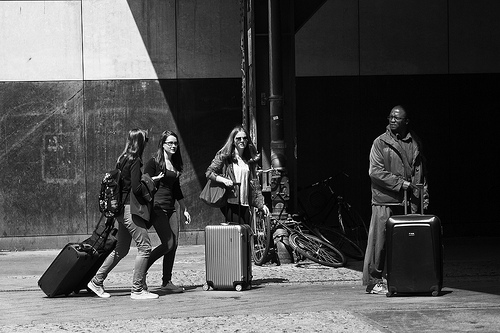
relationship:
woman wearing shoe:
[87, 128, 166, 301] [132, 290, 160, 300]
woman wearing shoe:
[87, 128, 166, 301] [88, 280, 111, 301]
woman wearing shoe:
[144, 129, 193, 293] [158, 283, 185, 293]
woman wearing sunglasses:
[205, 125, 271, 287] [233, 136, 249, 143]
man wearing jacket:
[362, 106, 429, 296] [369, 125, 429, 214]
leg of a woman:
[87, 214, 132, 297] [87, 128, 166, 301]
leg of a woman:
[120, 206, 161, 300] [87, 128, 166, 301]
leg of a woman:
[147, 203, 178, 268] [144, 129, 193, 293]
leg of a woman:
[161, 235, 185, 292] [144, 129, 193, 293]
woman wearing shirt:
[205, 125, 271, 287] [232, 154, 249, 209]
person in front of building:
[362, 106, 429, 296] [1, 2, 499, 237]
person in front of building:
[205, 125, 271, 287] [1, 2, 499, 237]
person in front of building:
[144, 129, 193, 293] [1, 2, 499, 237]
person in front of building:
[87, 128, 166, 301] [1, 2, 499, 237]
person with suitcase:
[362, 106, 429, 296] [384, 214, 441, 297]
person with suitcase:
[205, 125, 271, 287] [205, 222, 253, 290]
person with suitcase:
[87, 128, 166, 301] [38, 239, 101, 296]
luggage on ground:
[384, 214, 441, 297] [1, 245, 500, 333]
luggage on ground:
[205, 222, 253, 290] [1, 245, 500, 333]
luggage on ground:
[38, 239, 101, 296] [1, 245, 500, 333]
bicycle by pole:
[267, 208, 368, 267] [267, 2, 298, 265]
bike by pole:
[251, 197, 275, 264] [267, 2, 298, 265]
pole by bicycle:
[267, 2, 298, 265] [267, 208, 368, 267]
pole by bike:
[267, 2, 298, 265] [251, 197, 275, 264]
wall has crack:
[1, 2, 499, 237] [1, 83, 85, 161]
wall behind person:
[1, 2, 499, 237] [362, 106, 429, 296]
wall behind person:
[1, 2, 499, 237] [205, 125, 271, 287]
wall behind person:
[1, 2, 499, 237] [144, 129, 193, 293]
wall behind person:
[1, 2, 499, 237] [87, 128, 166, 301]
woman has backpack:
[87, 128, 166, 301] [97, 157, 142, 218]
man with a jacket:
[362, 106, 429, 296] [369, 125, 429, 214]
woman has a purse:
[205, 125, 271, 287] [197, 147, 233, 205]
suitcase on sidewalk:
[384, 214, 441, 297] [1, 276, 499, 332]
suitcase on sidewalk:
[205, 222, 253, 290] [1, 276, 499, 332]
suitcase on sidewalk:
[38, 239, 101, 296] [1, 276, 499, 332]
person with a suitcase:
[362, 106, 429, 296] [384, 214, 441, 297]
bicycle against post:
[267, 208, 368, 267] [267, 2, 298, 265]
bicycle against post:
[251, 197, 275, 264] [267, 2, 298, 265]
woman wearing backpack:
[87, 128, 166, 301] [97, 157, 142, 218]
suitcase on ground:
[384, 214, 441, 297] [1, 245, 500, 333]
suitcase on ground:
[205, 222, 253, 290] [1, 245, 500, 333]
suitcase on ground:
[38, 239, 101, 296] [1, 245, 500, 333]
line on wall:
[78, 4, 90, 234] [1, 2, 499, 237]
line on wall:
[176, 7, 180, 236] [1, 2, 499, 237]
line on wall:
[355, 5, 364, 175] [1, 2, 499, 237]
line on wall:
[446, 1, 454, 276] [1, 2, 499, 237]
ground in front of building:
[1, 245, 500, 333] [1, 2, 499, 237]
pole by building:
[267, 2, 298, 265] [1, 2, 499, 237]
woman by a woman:
[87, 128, 166, 301] [144, 129, 193, 293]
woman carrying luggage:
[87, 128, 166, 301] [38, 239, 101, 296]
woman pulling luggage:
[87, 128, 166, 301] [36, 213, 116, 299]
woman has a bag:
[87, 128, 166, 301] [97, 157, 142, 218]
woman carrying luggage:
[87, 128, 166, 301] [36, 213, 116, 299]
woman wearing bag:
[205, 125, 271, 287] [197, 147, 233, 205]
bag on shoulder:
[197, 147, 233, 205] [221, 152, 234, 163]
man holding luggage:
[362, 106, 429, 296] [384, 214, 441, 297]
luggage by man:
[384, 214, 441, 297] [362, 106, 429, 296]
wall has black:
[1, 2, 499, 237] [1, 75, 499, 236]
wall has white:
[1, 2, 499, 237] [1, 1, 500, 84]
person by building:
[362, 106, 429, 296] [1, 2, 499, 237]